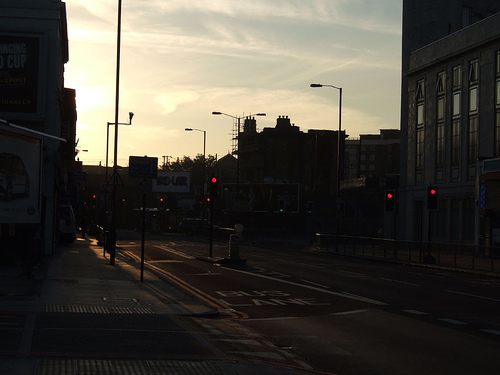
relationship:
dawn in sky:
[58, 8, 458, 268] [65, 0, 410, 166]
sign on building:
[155, 168, 193, 195] [128, 156, 158, 237]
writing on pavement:
[214, 288, 329, 312] [116, 227, 498, 372]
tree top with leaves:
[169, 146, 227, 185] [176, 133, 221, 191]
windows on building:
[408, 81, 485, 186] [398, 1, 498, 287]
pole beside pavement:
[110, 0, 122, 266] [116, 227, 498, 372]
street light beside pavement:
[303, 77, 348, 250] [116, 227, 498, 372]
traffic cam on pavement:
[107, 111, 135, 257] [116, 227, 498, 372]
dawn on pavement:
[58, 8, 458, 268] [116, 227, 498, 372]